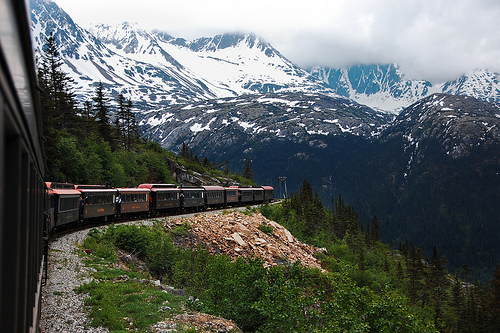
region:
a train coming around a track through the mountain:
[6, 0, 285, 234]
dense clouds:
[261, 7, 496, 63]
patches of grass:
[88, 250, 174, 328]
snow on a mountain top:
[167, 46, 282, 87]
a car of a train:
[117, 185, 147, 210]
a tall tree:
[42, 30, 83, 125]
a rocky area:
[218, 217, 310, 259]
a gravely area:
[53, 257, 83, 329]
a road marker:
[277, 173, 289, 198]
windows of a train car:
[159, 190, 179, 200]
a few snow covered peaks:
[81, 12, 475, 129]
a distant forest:
[261, 123, 476, 232]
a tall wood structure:
[273, 170, 295, 203]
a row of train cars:
[59, 177, 294, 219]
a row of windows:
[116, 188, 158, 206]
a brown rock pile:
[215, 210, 320, 260]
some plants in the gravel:
[54, 232, 94, 289]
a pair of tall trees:
[113, 92, 149, 160]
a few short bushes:
[145, 225, 440, 332]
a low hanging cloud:
[189, 15, 484, 110]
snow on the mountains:
[178, 41, 262, 90]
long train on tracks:
[95, 162, 252, 247]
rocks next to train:
[211, 195, 285, 260]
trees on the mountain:
[303, 191, 393, 267]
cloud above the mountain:
[360, 16, 443, 59]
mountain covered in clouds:
[189, 19, 268, 80]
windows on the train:
[81, 186, 118, 214]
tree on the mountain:
[41, 30, 83, 110]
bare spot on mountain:
[346, 63, 386, 95]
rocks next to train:
[56, 263, 91, 313]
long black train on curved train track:
[3, 0, 278, 332]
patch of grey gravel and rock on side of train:
[53, 247, 75, 297]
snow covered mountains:
[45, 2, 498, 107]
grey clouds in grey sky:
[305, 8, 477, 61]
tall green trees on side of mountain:
[304, 187, 442, 300]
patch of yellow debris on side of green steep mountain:
[197, 212, 297, 261]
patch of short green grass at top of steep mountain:
[109, 283, 161, 311]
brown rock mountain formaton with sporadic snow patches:
[400, 93, 496, 159]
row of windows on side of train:
[78, 191, 116, 207]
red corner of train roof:
[135, 182, 155, 191]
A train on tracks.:
[36, 186, 274, 222]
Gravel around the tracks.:
[37, 292, 85, 312]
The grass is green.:
[173, 267, 246, 291]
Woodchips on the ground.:
[247, 235, 304, 259]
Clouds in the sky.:
[357, 7, 432, 43]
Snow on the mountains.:
[199, 56, 266, 77]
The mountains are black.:
[432, 109, 496, 145]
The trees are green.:
[283, 187, 358, 230]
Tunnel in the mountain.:
[262, 170, 303, 204]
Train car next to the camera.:
[0, 204, 50, 260]